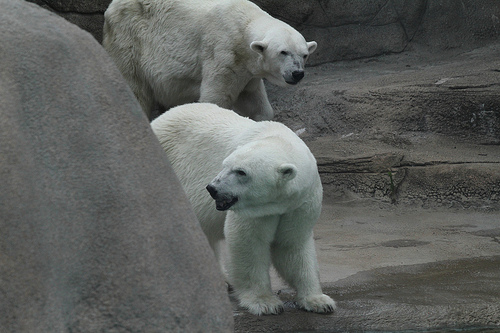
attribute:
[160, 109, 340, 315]
bear — here, looking, dirty, white, walking, big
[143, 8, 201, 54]
fur — white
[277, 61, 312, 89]
nose — black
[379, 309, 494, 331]
water — here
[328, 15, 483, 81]
wall — rocks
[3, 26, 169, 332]
rock — large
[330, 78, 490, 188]
ledges — rocks